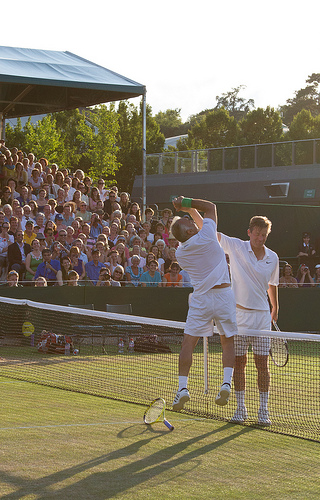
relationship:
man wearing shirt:
[85, 248, 105, 276] [83, 261, 103, 276]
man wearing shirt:
[171, 197, 279, 426] [215, 229, 297, 324]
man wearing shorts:
[171, 197, 279, 426] [226, 303, 283, 355]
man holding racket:
[217, 207, 291, 426] [266, 312, 292, 368]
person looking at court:
[80, 221, 96, 251] [0, 286, 319, 497]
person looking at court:
[20, 234, 47, 276] [0, 286, 319, 497]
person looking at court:
[75, 198, 93, 225] [0, 286, 319, 497]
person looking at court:
[109, 264, 127, 284] [0, 286, 319, 497]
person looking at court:
[141, 258, 163, 286] [0, 286, 319, 497]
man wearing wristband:
[170, 195, 239, 411] [180, 196, 192, 207]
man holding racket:
[171, 197, 279, 426] [269, 320, 289, 366]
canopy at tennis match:
[0, 41, 148, 120] [4, 195, 318, 492]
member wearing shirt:
[110, 242, 162, 279] [146, 259, 170, 277]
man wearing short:
[170, 195, 239, 411] [184, 286, 239, 339]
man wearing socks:
[170, 195, 239, 411] [161, 348, 273, 396]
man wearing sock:
[170, 195, 239, 411] [178, 376, 189, 393]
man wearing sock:
[170, 195, 239, 411] [222, 365, 233, 382]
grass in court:
[1, 341, 317, 497] [0, 286, 319, 497]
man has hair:
[173, 197, 280, 424] [245, 208, 275, 234]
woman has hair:
[128, 251, 143, 284] [130, 253, 141, 264]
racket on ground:
[142, 396, 175, 431] [1, 336, 318, 498]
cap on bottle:
[117, 336, 123, 341] [115, 334, 127, 354]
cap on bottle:
[129, 336, 134, 342] [127, 335, 138, 351]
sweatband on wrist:
[179, 194, 194, 210] [177, 195, 195, 208]